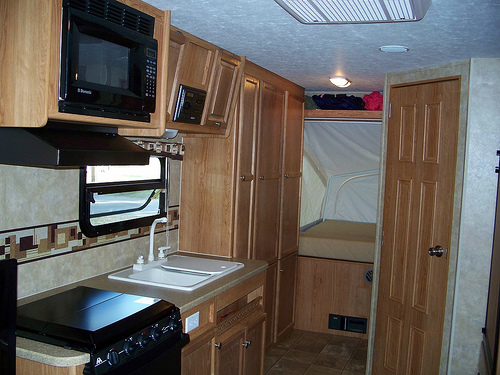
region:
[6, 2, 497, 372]
an image of a rv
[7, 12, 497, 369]
a scene during the day time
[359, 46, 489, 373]
a door to the bathroom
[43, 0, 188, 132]
a black microwave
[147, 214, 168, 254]
white faucet on sink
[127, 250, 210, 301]
white sink in kitchen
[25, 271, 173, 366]
black range in kitchen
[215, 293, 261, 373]
black cabinets under sink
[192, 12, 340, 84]
white ceiling over kitchen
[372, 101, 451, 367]
black door for closet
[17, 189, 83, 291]
brown and white backsplash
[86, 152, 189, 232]
black frame on window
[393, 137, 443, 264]
A door in the room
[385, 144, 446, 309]
A wooden door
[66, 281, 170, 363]
An oven in the kitchen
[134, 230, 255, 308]
A sink in the kitchen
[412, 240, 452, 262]
A door handle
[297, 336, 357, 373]
Tiles on the floor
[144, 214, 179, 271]
Taps on the sink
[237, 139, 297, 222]
Cabinets in the kitchen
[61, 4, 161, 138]
black microwave over range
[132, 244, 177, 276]
white handles on sink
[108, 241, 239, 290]
white basin on sink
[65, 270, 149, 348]
black range near sink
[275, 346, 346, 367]
brown tile on floor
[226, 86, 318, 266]
brown cabinets near sink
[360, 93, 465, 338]
brown door across from sink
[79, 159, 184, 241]
black frame on window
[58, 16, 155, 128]
black microwave in kitchen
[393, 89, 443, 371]
brown door near kitchen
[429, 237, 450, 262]
nickel handle on door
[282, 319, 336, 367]
tile floor is brown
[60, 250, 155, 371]
black range in kitchen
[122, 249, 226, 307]
white sink on counter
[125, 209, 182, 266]
white faucet on sink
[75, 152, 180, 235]
black cover on window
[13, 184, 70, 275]
grey and brown wall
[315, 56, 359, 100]
white light on ceiling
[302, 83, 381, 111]
clothes on top of a shelf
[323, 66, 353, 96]
light on top of the ceiling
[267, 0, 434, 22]
vent on the ceiling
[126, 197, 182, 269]
white faucet on the sink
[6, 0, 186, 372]
a microwave above a stove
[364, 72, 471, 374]
the door is brown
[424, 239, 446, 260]
the knob is color silver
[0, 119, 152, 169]
Oven range above the dishwasher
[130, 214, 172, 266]
White faucet above the sink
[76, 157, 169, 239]
Window behind the faucet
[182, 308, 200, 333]
White outlet next to the dishwasher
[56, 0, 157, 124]
Microwave above the oven range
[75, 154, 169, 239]
Small window is opened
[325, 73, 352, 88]
Small light is on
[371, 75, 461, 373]
brown door is closed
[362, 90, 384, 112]
Pink bag near the light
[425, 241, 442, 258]
Silver door knob on the brown door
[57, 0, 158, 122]
black microwave above stove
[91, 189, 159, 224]
window above kitchen sink